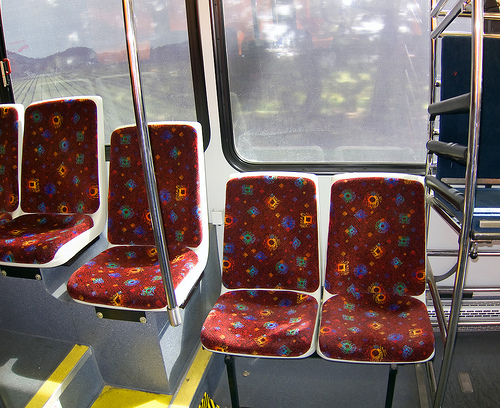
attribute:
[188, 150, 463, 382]
two seats — multicolored, colorful, deep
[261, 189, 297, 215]
design — yellow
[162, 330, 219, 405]
line — yellow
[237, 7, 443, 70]
light — streaming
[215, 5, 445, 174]
window — large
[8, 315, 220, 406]
floor — gray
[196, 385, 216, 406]
stripes — yellow, black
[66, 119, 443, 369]
three seats — here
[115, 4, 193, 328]
pole — metal, shiny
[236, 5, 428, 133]
trees — outside window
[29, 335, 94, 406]
caution tape — yellow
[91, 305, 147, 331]
plate — metal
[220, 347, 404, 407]
legs — black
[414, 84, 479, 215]
three poles — horizontal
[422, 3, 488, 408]
two poles — vertical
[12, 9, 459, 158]
field — outside window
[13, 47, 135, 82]
mountain — outside window